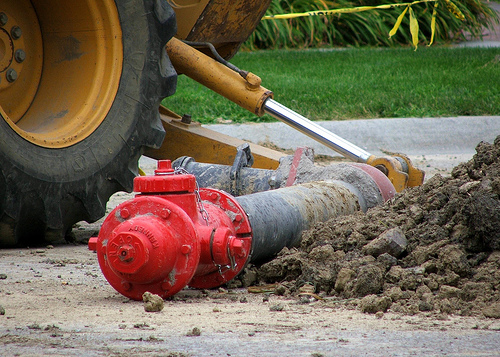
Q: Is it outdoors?
A: Yes, it is outdoors.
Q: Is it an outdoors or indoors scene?
A: It is outdoors.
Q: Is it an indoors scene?
A: No, it is outdoors.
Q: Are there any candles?
A: No, there are no candles.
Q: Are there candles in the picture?
A: No, there are no candles.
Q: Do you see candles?
A: No, there are no candles.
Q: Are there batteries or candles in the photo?
A: No, there are no candles or batteries.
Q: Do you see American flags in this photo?
A: No, there are no American flags.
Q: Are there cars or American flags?
A: No, there are no American flags or cars.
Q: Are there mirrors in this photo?
A: No, there are no mirrors.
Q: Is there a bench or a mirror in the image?
A: No, there are no mirrors or benches.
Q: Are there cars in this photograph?
A: No, there are no cars.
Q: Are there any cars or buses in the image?
A: No, there are no cars or buses.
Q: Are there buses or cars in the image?
A: No, there are no cars or buses.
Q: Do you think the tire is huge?
A: Yes, the tire is huge.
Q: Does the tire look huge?
A: Yes, the tire is huge.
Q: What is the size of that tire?
A: The tire is huge.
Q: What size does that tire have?
A: The tire has huge size.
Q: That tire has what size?
A: The tire is huge.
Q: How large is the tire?
A: The tire is huge.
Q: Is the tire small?
A: No, the tire is huge.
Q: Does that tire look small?
A: No, the tire is huge.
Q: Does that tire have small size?
A: No, the tire is huge.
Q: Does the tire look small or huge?
A: The tire is huge.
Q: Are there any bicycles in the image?
A: No, there are no bicycles.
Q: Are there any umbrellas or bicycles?
A: No, there are no bicycles or umbrellas.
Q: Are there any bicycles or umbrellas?
A: No, there are no bicycles or umbrellas.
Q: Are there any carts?
A: No, there are no carts.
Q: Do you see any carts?
A: No, there are no carts.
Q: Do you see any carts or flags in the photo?
A: No, there are no carts or flags.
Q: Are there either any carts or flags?
A: No, there are no carts or flags.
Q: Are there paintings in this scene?
A: No, there are no paintings.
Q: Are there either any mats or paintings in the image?
A: No, there are no paintings or mats.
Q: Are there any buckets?
A: No, there are no buckets.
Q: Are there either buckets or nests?
A: No, there are no buckets or nests.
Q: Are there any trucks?
A: Yes, there is a truck.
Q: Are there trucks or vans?
A: Yes, there is a truck.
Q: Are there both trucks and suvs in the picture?
A: No, there is a truck but no suvs.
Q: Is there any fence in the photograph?
A: No, there are no fences.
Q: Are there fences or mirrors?
A: No, there are no fences or mirrors.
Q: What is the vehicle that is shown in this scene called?
A: The vehicle is a truck.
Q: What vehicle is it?
A: The vehicle is a truck.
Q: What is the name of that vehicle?
A: This is a truck.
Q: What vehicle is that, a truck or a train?
A: This is a truck.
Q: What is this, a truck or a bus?
A: This is a truck.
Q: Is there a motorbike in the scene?
A: No, there are no motorcycles.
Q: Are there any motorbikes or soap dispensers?
A: No, there are no motorbikes or soap dispensers.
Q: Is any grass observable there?
A: Yes, there is grass.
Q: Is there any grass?
A: Yes, there is grass.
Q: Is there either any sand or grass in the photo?
A: Yes, there is grass.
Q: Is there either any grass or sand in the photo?
A: Yes, there is grass.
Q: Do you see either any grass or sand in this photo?
A: Yes, there is grass.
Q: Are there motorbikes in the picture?
A: No, there are no motorbikes.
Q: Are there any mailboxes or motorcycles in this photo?
A: No, there are no motorcycles or mailboxes.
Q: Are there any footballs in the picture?
A: No, there are no footballs.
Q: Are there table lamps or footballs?
A: No, there are no footballs or table lamps.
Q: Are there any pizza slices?
A: No, there are no pizza slices.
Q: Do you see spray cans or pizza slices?
A: No, there are no pizza slices or spray cans.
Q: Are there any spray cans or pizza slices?
A: No, there are no pizza slices or spray cans.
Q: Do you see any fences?
A: No, there are no fences.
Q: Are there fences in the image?
A: No, there are no fences.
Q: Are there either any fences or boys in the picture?
A: No, there are no fences or boys.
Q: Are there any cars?
A: No, there are no cars.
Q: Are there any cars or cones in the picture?
A: No, there are no cars or cones.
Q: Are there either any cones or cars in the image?
A: No, there are no cars or cones.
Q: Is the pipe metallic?
A: Yes, the pipe is metallic.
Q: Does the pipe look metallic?
A: Yes, the pipe is metallic.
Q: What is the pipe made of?
A: The pipe is made of metal.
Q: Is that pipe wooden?
A: No, the pipe is metallic.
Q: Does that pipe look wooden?
A: No, the pipe is metallic.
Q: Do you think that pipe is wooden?
A: No, the pipe is metallic.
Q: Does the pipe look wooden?
A: No, the pipe is metallic.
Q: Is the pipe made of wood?
A: No, the pipe is made of metal.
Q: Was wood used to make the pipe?
A: No, the pipe is made of metal.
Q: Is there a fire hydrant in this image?
A: Yes, there is a fire hydrant.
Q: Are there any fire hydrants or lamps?
A: Yes, there is a fire hydrant.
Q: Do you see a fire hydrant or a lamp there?
A: Yes, there is a fire hydrant.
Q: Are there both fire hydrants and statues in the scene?
A: No, there is a fire hydrant but no statues.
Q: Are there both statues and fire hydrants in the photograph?
A: No, there is a fire hydrant but no statues.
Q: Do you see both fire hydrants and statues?
A: No, there is a fire hydrant but no statues.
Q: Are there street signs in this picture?
A: No, there are no street signs.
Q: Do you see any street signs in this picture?
A: No, there are no street signs.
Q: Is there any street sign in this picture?
A: No, there are no street signs.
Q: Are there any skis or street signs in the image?
A: No, there are no street signs or skis.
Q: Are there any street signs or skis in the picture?
A: No, there are no street signs or skis.